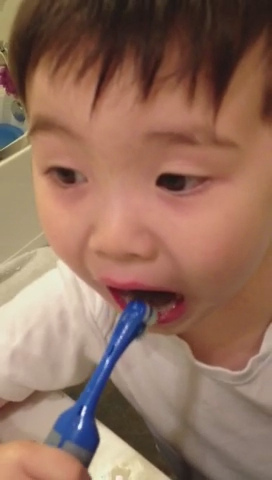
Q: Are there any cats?
A: No, there are no cats.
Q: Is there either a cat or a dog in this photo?
A: No, there are no cats or dogs.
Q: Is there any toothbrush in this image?
A: Yes, there is a toothbrush.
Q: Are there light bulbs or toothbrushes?
A: Yes, there is a toothbrush.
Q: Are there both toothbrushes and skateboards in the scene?
A: No, there is a toothbrush but no skateboards.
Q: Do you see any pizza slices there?
A: No, there are no pizza slices.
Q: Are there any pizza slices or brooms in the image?
A: No, there are no pizza slices or brooms.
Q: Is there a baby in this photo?
A: Yes, there is a baby.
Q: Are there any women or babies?
A: Yes, there is a baby.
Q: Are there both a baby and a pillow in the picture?
A: No, there is a baby but no pillows.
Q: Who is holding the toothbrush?
A: The baby is holding the toothbrush.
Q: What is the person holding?
A: The baby is holding the toothbrush.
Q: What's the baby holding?
A: The baby is holding the toothbrush.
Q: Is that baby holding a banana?
A: No, the baby is holding the toothbrush.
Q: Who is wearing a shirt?
A: The baby is wearing a shirt.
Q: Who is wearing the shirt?
A: The baby is wearing a shirt.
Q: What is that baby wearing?
A: The baby is wearing a shirt.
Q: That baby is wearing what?
A: The baby is wearing a shirt.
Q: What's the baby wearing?
A: The baby is wearing a shirt.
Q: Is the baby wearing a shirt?
A: Yes, the baby is wearing a shirt.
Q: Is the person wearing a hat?
A: No, the baby is wearing a shirt.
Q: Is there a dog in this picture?
A: No, there are no dogs.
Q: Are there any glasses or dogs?
A: No, there are no dogs or glasses.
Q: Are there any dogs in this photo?
A: No, there are no dogs.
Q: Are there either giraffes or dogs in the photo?
A: No, there are no dogs or giraffes.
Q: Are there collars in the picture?
A: Yes, there is a collar.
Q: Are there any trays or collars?
A: Yes, there is a collar.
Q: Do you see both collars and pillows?
A: No, there is a collar but no pillows.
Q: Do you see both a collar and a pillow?
A: No, there is a collar but no pillows.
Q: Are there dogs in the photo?
A: No, there are no dogs.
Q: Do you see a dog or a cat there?
A: No, there are no dogs or cats.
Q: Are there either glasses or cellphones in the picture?
A: No, there are no glasses or cellphones.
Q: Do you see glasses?
A: No, there are no glasses.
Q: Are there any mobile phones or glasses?
A: No, there are no glasses or mobile phones.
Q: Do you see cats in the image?
A: No, there are no cats.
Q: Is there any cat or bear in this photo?
A: No, there are no cats or bears.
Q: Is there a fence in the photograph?
A: No, there are no fences.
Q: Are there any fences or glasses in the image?
A: No, there are no fences or glasses.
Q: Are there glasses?
A: No, there are no glasses.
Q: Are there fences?
A: No, there are no fences.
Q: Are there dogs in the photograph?
A: No, there are no dogs.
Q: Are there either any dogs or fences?
A: No, there are no dogs or fences.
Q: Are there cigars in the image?
A: No, there are no cigars.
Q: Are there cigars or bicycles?
A: No, there are no cigars or bicycles.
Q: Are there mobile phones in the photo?
A: No, there are no mobile phones.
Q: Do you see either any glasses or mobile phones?
A: No, there are no mobile phones or glasses.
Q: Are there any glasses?
A: No, there are no glasses.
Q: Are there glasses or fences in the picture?
A: No, there are no glasses or fences.